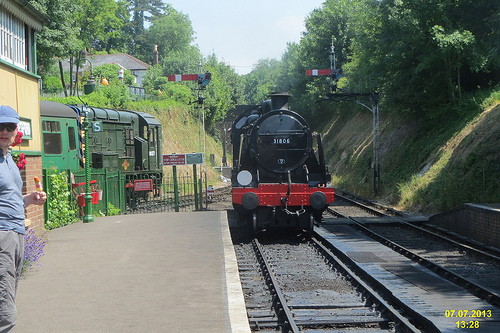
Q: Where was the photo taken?
A: It was taken at the train station.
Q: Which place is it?
A: It is a train station.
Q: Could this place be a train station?
A: Yes, it is a train station.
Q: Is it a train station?
A: Yes, it is a train station.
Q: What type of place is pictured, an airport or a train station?
A: It is a train station.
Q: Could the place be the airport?
A: No, it is the train station.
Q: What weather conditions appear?
A: It is cloudy.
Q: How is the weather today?
A: It is cloudy.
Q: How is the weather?
A: It is cloudy.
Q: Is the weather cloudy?
A: Yes, it is cloudy.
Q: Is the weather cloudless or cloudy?
A: It is cloudy.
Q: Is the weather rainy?
A: No, it is cloudy.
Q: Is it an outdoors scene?
A: Yes, it is outdoors.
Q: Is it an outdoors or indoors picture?
A: It is outdoors.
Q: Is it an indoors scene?
A: No, it is outdoors.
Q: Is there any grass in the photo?
A: Yes, there is grass.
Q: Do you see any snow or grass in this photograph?
A: Yes, there is grass.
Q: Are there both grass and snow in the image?
A: No, there is grass but no snow.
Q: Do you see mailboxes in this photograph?
A: No, there are no mailboxes.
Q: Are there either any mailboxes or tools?
A: No, there are no mailboxes or tools.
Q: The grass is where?
A: The grass is on the hill.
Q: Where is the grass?
A: The grass is on the hill.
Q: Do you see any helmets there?
A: No, there are no helmets.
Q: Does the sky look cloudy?
A: Yes, the sky is cloudy.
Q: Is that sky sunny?
A: No, the sky is cloudy.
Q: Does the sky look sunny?
A: No, the sky is cloudy.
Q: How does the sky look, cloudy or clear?
A: The sky is cloudy.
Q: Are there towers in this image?
A: No, there are no towers.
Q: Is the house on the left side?
A: Yes, the house is on the left of the image.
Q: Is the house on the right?
A: No, the house is on the left of the image.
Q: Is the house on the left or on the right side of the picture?
A: The house is on the left of the image.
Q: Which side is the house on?
A: The house is on the left of the image.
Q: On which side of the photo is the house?
A: The house is on the left of the image.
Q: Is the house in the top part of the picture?
A: Yes, the house is in the top of the image.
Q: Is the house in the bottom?
A: No, the house is in the top of the image.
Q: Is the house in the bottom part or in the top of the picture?
A: The house is in the top of the image.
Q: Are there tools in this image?
A: No, there are no tools.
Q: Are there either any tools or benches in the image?
A: No, there are no tools or benches.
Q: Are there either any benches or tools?
A: No, there are no tools or benches.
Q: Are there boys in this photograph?
A: No, there are no boys.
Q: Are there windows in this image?
A: Yes, there are windows.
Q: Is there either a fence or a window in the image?
A: Yes, there are windows.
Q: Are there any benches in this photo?
A: No, there are no benches.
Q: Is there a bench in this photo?
A: No, there are no benches.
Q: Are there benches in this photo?
A: No, there are no benches.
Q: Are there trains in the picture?
A: Yes, there is a train.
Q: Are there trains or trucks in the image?
A: Yes, there is a train.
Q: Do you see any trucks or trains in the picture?
A: Yes, there is a train.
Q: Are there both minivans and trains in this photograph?
A: No, there is a train but no minivans.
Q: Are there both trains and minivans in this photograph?
A: No, there is a train but no minivans.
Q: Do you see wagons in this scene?
A: No, there are no wagons.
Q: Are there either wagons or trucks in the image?
A: No, there are no wagons or trucks.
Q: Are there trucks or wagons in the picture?
A: No, there are no wagons or trucks.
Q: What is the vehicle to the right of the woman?
A: The vehicle is a train.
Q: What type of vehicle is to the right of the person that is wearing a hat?
A: The vehicle is a train.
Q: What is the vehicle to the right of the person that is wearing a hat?
A: The vehicle is a train.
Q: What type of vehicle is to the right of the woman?
A: The vehicle is a train.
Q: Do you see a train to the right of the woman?
A: Yes, there is a train to the right of the woman.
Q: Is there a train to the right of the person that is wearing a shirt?
A: Yes, there is a train to the right of the woman.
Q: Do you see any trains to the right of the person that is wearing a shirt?
A: Yes, there is a train to the right of the woman.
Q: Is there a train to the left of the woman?
A: No, the train is to the right of the woman.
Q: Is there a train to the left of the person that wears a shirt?
A: No, the train is to the right of the woman.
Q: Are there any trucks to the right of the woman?
A: No, there is a train to the right of the woman.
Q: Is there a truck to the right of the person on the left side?
A: No, there is a train to the right of the woman.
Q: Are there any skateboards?
A: No, there are no skateboards.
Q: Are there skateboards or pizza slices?
A: No, there are no skateboards or pizza slices.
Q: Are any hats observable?
A: Yes, there is a hat.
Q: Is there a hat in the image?
A: Yes, there is a hat.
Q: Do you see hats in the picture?
A: Yes, there is a hat.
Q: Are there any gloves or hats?
A: Yes, there is a hat.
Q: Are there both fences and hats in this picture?
A: Yes, there are both a hat and a fence.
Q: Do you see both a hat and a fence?
A: Yes, there are both a hat and a fence.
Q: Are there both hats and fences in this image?
A: Yes, there are both a hat and a fence.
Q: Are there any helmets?
A: No, there are no helmets.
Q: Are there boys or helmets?
A: No, there are no helmets or boys.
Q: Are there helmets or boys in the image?
A: No, there are no helmets or boys.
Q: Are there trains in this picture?
A: Yes, there is a train.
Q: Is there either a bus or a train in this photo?
A: Yes, there is a train.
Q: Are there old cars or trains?
A: Yes, there is an old train.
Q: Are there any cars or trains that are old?
A: Yes, the train is old.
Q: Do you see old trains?
A: Yes, there is an old train.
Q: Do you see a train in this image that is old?
A: Yes, there is a train that is old.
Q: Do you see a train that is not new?
A: Yes, there is a old train.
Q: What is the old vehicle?
A: The vehicle is a train.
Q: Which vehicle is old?
A: The vehicle is a train.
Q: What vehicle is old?
A: The vehicle is a train.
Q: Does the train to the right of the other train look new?
A: No, the train is old.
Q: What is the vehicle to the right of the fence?
A: The vehicle is a train.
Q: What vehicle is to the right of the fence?
A: The vehicle is a train.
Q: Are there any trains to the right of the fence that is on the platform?
A: Yes, there is a train to the right of the fence.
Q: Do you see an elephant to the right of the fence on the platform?
A: No, there is a train to the right of the fence.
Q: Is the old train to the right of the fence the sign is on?
A: Yes, the train is to the right of the fence.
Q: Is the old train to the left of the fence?
A: No, the train is to the right of the fence.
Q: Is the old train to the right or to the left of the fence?
A: The train is to the right of the fence.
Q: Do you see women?
A: Yes, there is a woman.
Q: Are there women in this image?
A: Yes, there is a woman.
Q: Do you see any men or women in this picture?
A: Yes, there is a woman.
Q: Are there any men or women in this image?
A: Yes, there is a woman.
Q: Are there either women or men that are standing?
A: Yes, the woman is standing.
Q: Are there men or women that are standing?
A: Yes, the woman is standing.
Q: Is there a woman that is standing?
A: Yes, there is a woman that is standing.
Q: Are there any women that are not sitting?
A: Yes, there is a woman that is standing.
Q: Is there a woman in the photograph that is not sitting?
A: Yes, there is a woman that is standing.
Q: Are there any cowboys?
A: No, there are no cowboys.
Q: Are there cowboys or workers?
A: No, there are no cowboys or workers.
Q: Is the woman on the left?
A: Yes, the woman is on the left of the image.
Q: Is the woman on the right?
A: No, the woman is on the left of the image.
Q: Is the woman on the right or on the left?
A: The woman is on the left of the image.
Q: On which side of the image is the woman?
A: The woman is on the left of the image.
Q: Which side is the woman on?
A: The woman is on the left of the image.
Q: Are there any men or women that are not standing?
A: No, there is a woman but she is standing.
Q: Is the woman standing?
A: Yes, the woman is standing.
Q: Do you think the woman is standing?
A: Yes, the woman is standing.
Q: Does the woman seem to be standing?
A: Yes, the woman is standing.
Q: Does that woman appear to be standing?
A: Yes, the woman is standing.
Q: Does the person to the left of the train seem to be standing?
A: Yes, the woman is standing.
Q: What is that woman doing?
A: The woman is standing.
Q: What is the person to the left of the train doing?
A: The woman is standing.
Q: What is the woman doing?
A: The woman is standing.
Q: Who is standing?
A: The woman is standing.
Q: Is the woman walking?
A: No, the woman is standing.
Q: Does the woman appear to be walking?
A: No, the woman is standing.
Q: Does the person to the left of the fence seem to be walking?
A: No, the woman is standing.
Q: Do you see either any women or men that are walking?
A: No, there is a woman but she is standing.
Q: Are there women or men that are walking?
A: No, there is a woman but she is standing.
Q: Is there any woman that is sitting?
A: No, there is a woman but she is standing.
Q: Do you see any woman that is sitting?
A: No, there is a woman but she is standing.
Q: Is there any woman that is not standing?
A: No, there is a woman but she is standing.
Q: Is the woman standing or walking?
A: The woman is standing.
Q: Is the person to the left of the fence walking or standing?
A: The woman is standing.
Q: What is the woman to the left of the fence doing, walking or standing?
A: The woman is standing.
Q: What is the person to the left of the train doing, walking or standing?
A: The woman is standing.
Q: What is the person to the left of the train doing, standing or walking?
A: The woman is standing.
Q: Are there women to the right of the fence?
A: No, the woman is to the left of the fence.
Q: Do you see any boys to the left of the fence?
A: No, there is a woman to the left of the fence.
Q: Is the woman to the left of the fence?
A: Yes, the woman is to the left of the fence.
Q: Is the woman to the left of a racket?
A: No, the woman is to the left of the fence.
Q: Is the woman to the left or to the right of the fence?
A: The woman is to the left of the fence.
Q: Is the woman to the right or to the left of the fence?
A: The woman is to the left of the fence.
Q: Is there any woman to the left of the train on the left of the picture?
A: Yes, there is a woman to the left of the train.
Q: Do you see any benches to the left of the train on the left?
A: No, there is a woman to the left of the train.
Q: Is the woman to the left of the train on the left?
A: Yes, the woman is to the left of the train.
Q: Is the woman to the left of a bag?
A: No, the woman is to the left of the train.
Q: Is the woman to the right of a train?
A: No, the woman is to the left of a train.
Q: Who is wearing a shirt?
A: The woman is wearing a shirt.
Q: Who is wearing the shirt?
A: The woman is wearing a shirt.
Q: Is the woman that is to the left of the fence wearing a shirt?
A: Yes, the woman is wearing a shirt.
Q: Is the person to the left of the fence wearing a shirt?
A: Yes, the woman is wearing a shirt.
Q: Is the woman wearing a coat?
A: No, the woman is wearing a shirt.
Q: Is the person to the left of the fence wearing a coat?
A: No, the woman is wearing a shirt.